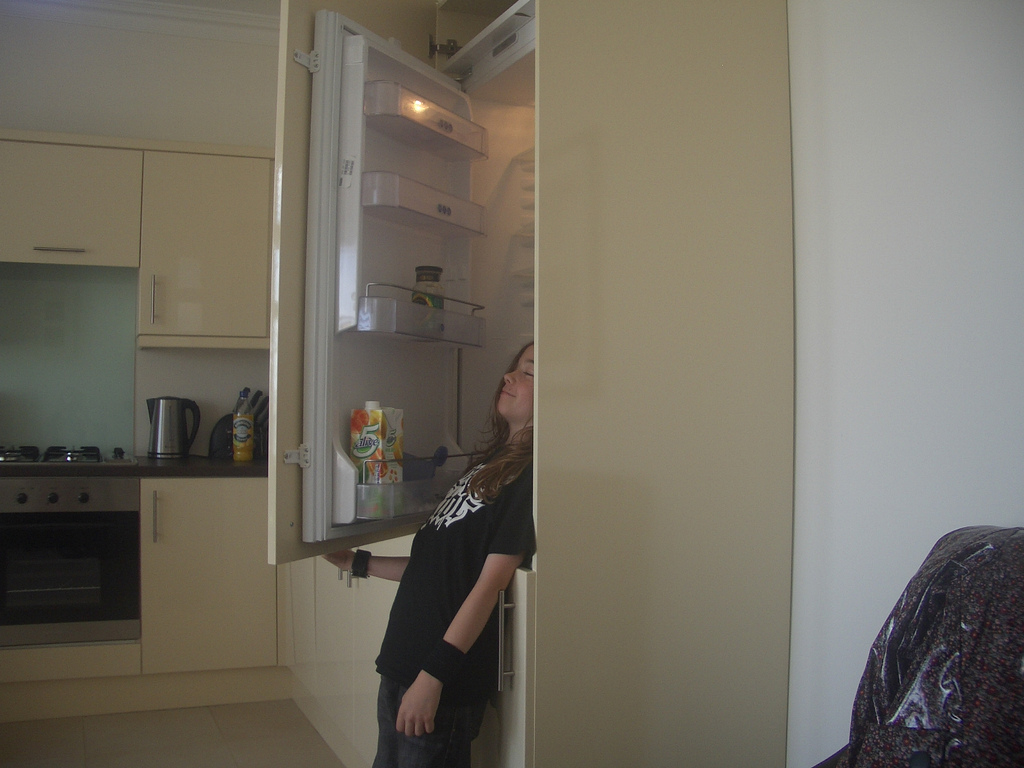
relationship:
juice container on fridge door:
[333, 393, 406, 511] [265, 0, 494, 574]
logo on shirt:
[415, 453, 502, 527] [371, 441, 536, 707]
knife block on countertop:
[196, 386, 273, 462] [140, 441, 276, 470]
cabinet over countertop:
[4, 143, 145, 271] [129, 450, 256, 477]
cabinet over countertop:
[126, 153, 288, 347] [129, 450, 256, 477]